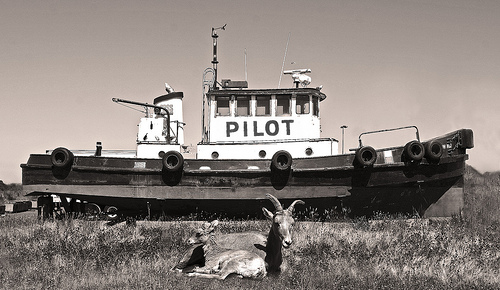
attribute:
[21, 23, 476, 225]
ship — black, white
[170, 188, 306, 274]
goat — laying, resting, sitting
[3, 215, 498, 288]
grass — tall, patchy